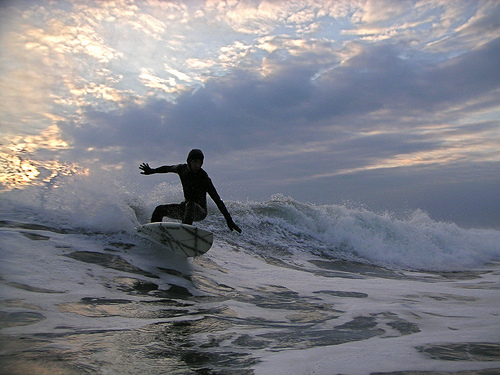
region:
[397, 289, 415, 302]
part of the wave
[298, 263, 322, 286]
part of the sea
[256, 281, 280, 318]
part of the ocean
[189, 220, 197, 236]
part of the board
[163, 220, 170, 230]
edge of a board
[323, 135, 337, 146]
parr of a cloud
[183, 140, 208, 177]
face of a man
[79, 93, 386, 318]
a man surfing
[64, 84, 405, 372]
a man on a surfboard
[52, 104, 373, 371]
a man surfing in the water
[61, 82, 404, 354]
a man surfing a wave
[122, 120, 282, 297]
a man on a white surfboard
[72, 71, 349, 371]
a man surfing a body of water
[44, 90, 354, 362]
a body of water with a sufre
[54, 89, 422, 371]
a surfer on the water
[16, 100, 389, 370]
a surfer riding a wave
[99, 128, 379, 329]
a surfer on a surfboard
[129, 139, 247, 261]
a surfer on a wave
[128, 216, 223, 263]
a white surfboard on the water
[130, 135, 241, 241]
surfer has extended arms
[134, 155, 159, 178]
the hand is extended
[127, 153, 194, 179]
a extended right hand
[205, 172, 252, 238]
a extended left hand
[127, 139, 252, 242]
the surfer is crouched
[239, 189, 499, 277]
a big foamy wave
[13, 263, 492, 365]
foam in the water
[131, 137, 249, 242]
surfer wears black suit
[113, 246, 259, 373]
a reflection on the water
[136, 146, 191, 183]
right hand of man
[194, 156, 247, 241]
left hand of man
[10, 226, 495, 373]
foamy on the water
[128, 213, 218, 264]
a board on a wave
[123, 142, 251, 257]
man has short hair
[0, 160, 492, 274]
crest of a wave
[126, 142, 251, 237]
man is is crouched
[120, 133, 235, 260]
a person riding a surfboard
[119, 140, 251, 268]
a person surfing on the ocean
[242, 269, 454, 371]
white ocean foam on the water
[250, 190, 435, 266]
a cresting wave rolling over itself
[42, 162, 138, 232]
white ocean spray from the back of the surfboard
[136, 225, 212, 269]
a white surfboard in the water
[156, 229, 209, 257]
black lines on the bottom of the surfboard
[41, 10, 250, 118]
cloudy blue skies over the ocean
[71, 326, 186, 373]
calm blue water of the ocean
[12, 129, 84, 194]
light of the setting sun through the clouds